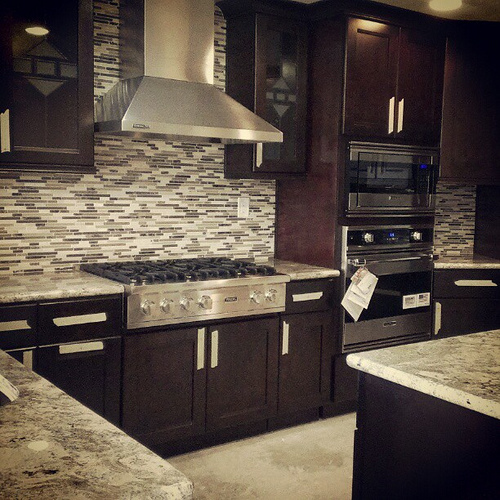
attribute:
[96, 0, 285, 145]
overhead vent — stainless steel 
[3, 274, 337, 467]
cabinets — dark , wood 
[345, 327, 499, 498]
kitchen island — marble 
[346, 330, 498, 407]
marble countertop — marble 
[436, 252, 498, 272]
marble countertop — marble 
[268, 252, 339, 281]
marble countertop — marble 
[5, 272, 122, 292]
marble countertop — marble 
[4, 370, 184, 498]
marble countertop — marble 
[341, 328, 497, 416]
counter — marble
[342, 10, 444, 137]
cabinet — dark, wood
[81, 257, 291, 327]
oven range — stainless steel 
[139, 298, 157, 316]
knobs — silver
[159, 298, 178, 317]
knobs — silver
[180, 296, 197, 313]
knobs — silver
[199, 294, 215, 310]
knobs — silver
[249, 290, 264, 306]
knobs — silver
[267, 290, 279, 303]
knobs — silver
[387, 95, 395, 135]
tape — a strip